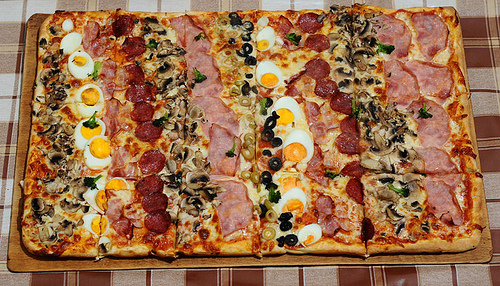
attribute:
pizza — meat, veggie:
[50, 31, 467, 196]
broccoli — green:
[388, 179, 402, 194]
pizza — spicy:
[16, 27, 478, 252]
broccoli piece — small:
[81, 108, 101, 130]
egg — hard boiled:
[270, 97, 303, 132]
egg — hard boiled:
[282, 129, 312, 169]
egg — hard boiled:
[280, 191, 306, 220]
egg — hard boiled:
[290, 227, 320, 241]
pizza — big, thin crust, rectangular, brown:
[21, 8, 484, 260]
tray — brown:
[4, 253, 28, 267]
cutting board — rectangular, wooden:
[8, 10, 488, 270]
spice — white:
[271, 120, 346, 174]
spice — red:
[395, 19, 475, 64]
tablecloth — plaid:
[2, 4, 496, 282]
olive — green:
[253, 224, 280, 249]